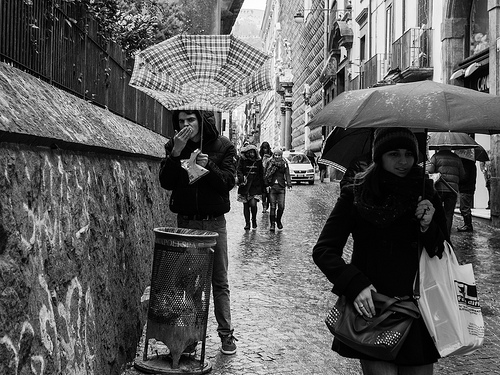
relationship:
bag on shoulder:
[325, 292, 422, 362] [339, 173, 369, 207]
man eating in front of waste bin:
[159, 111, 239, 356] [137, 221, 229, 373]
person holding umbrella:
[313, 126, 450, 358] [307, 76, 499, 133]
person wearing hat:
[313, 126, 450, 358] [370, 125, 419, 164]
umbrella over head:
[275, 70, 498, 132] [371, 124, 417, 180]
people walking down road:
[237, 140, 289, 234] [254, 273, 293, 367]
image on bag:
[451, 272, 493, 313] [400, 229, 488, 373]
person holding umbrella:
[307, 127, 472, 358] [121, 29, 283, 121]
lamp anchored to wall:
[272, 13, 314, 34] [320, 2, 448, 92]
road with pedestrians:
[141, 174, 498, 366] [173, 108, 242, 360]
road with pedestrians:
[141, 174, 498, 366] [236, 135, 268, 236]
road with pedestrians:
[141, 174, 498, 366] [268, 145, 292, 254]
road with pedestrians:
[141, 174, 498, 366] [314, 118, 471, 367]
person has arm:
[313, 126, 450, 358] [416, 163, 446, 261]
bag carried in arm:
[398, 225, 490, 356] [416, 163, 446, 261]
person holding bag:
[313, 126, 450, 358] [325, 296, 429, 360]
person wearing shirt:
[313, 126, 450, 358] [312, 165, 447, 306]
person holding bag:
[313, 126, 450, 358] [325, 292, 422, 362]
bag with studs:
[325, 292, 422, 362] [370, 329, 404, 349]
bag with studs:
[325, 292, 422, 362] [327, 304, 343, 330]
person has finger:
[313, 126, 450, 358] [355, 297, 372, 322]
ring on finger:
[354, 298, 367, 315] [355, 297, 372, 322]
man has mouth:
[158, 107, 237, 354] [181, 127, 196, 135]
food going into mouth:
[178, 147, 209, 183] [181, 127, 196, 135]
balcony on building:
[358, 12, 426, 90] [262, 24, 495, 239]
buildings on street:
[250, 2, 499, 212] [131, 148, 498, 373]